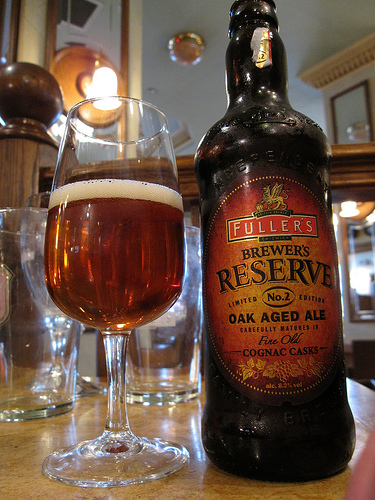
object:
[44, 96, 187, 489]
glass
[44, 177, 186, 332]
beer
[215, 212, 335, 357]
fuller's ale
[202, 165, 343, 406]
family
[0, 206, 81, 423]
glass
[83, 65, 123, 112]
light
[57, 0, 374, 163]
wall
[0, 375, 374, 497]
table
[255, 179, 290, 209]
flying lion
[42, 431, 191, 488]
base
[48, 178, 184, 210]
foam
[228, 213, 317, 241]
fuller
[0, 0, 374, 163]
ceiling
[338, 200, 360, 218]
light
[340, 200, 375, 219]
plaque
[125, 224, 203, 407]
glass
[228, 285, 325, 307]
limited no 2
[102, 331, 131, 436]
stem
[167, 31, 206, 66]
fixture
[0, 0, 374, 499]
bar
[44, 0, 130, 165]
mirror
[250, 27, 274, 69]
sticker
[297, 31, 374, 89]
moulding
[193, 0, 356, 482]
bottle